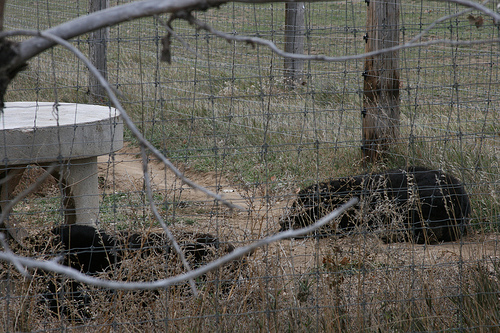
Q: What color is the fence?
A: Silver.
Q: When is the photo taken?
A: Day time.